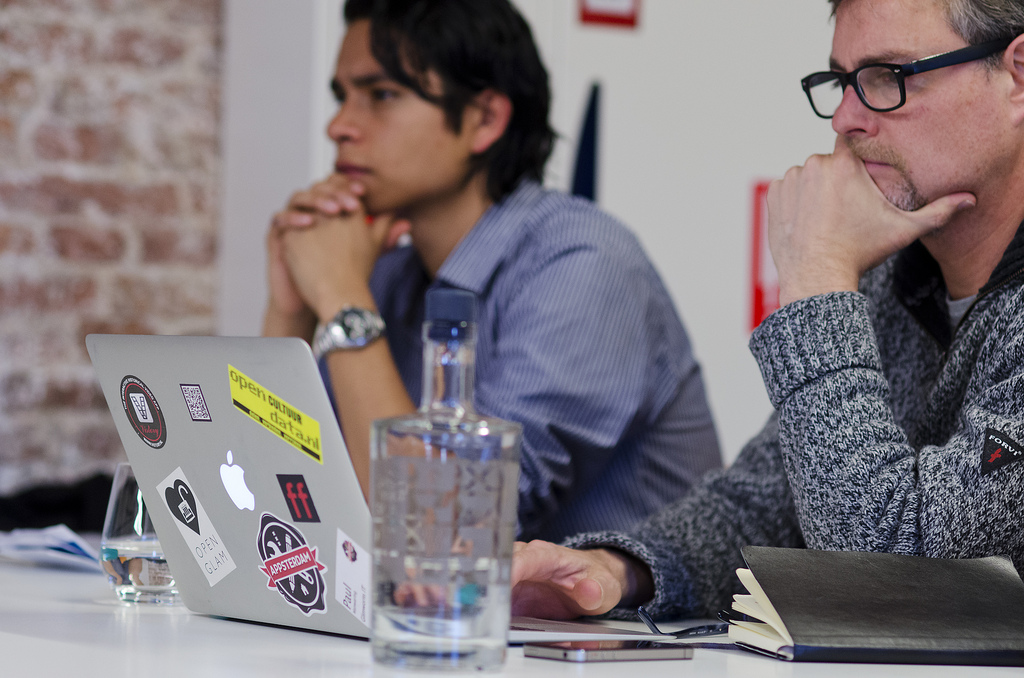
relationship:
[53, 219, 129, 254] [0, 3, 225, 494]
brick in wall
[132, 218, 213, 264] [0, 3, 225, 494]
brick in wall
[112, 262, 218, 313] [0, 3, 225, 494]
brick in wall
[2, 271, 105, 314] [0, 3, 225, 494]
brick in wall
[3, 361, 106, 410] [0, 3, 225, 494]
brick in wall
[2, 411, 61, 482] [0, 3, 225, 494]
brick in wall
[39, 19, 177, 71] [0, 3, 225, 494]
brick in wall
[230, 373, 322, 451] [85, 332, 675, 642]
sticker on laptop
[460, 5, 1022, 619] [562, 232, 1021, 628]
man wearing a sweater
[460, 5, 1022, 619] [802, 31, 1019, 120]
man wearing glasses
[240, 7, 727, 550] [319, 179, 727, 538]
man wearing button down